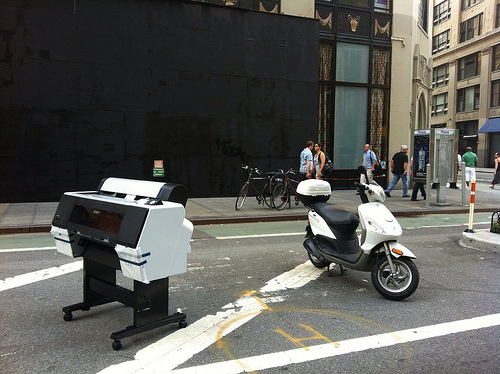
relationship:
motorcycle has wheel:
[295, 176, 417, 297] [376, 261, 418, 298]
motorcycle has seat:
[295, 176, 417, 297] [316, 200, 357, 228]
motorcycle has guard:
[295, 176, 417, 297] [359, 200, 401, 256]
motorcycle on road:
[295, 176, 417, 297] [5, 207, 500, 371]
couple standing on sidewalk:
[300, 140, 328, 183] [3, 184, 499, 228]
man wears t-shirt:
[389, 140, 408, 197] [391, 151, 405, 175]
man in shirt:
[362, 144, 378, 181] [361, 152, 376, 168]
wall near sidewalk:
[3, 1, 316, 200] [3, 184, 499, 228]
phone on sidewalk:
[408, 130, 456, 207] [3, 184, 499, 228]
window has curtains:
[319, 38, 385, 169] [371, 47, 384, 177]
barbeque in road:
[49, 174, 193, 353] [5, 207, 500, 371]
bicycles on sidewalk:
[234, 165, 302, 207] [3, 184, 499, 228]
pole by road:
[469, 176, 475, 233] [5, 207, 500, 371]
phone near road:
[408, 130, 456, 207] [5, 207, 500, 371]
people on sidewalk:
[295, 138, 498, 201] [3, 184, 499, 228]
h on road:
[275, 321, 332, 353] [5, 207, 500, 371]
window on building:
[319, 38, 385, 169] [175, 1, 429, 185]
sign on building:
[153, 159, 164, 178] [175, 1, 429, 185]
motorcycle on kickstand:
[295, 176, 417, 297] [325, 261, 347, 276]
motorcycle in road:
[295, 176, 417, 297] [5, 207, 500, 371]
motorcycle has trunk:
[295, 176, 417, 297] [294, 177, 332, 201]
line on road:
[113, 306, 499, 372] [5, 207, 500, 371]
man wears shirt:
[461, 149, 477, 189] [462, 154, 475, 166]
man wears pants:
[461, 149, 477, 189] [464, 167, 476, 185]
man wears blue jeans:
[389, 140, 408, 197] [386, 176, 407, 195]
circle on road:
[210, 312, 411, 374] [5, 207, 500, 371]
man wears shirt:
[362, 144, 378, 181] [361, 152, 376, 168]